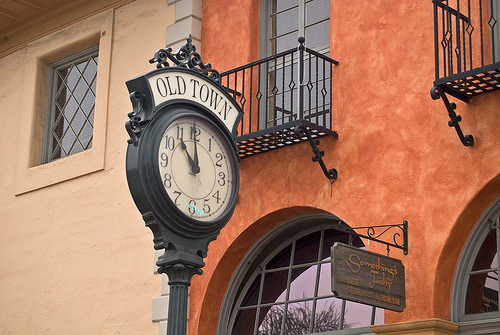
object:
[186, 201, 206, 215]
mark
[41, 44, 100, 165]
blinds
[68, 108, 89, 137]
pane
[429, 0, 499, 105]
balcony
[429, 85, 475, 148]
bracket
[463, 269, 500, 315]
window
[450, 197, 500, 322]
frame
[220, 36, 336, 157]
fence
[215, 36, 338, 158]
balcony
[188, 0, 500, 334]
building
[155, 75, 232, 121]
writing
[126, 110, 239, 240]
clock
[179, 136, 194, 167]
hand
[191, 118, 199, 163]
hand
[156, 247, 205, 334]
pole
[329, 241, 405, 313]
sign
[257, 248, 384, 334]
reflection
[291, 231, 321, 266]
window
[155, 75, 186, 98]
word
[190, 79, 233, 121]
word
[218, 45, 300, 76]
railing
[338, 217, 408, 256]
brace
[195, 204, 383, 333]
arch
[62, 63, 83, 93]
pane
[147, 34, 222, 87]
decoration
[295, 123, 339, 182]
brace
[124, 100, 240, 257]
frame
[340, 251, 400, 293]
name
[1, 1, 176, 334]
wall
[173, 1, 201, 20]
brick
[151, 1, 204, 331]
row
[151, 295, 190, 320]
brick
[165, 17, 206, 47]
brick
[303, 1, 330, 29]
window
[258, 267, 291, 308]
pane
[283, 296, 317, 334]
pane